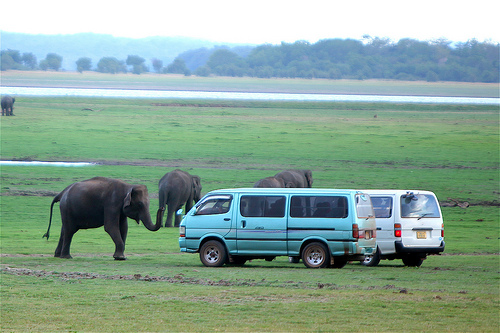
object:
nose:
[139, 198, 150, 215]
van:
[175, 187, 445, 268]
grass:
[158, 296, 217, 316]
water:
[64, 161, 91, 166]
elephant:
[41, 176, 166, 260]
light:
[393, 222, 402, 237]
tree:
[151, 35, 500, 80]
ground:
[164, 293, 319, 332]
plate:
[416, 230, 427, 239]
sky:
[209, 3, 253, 38]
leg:
[54, 217, 128, 252]